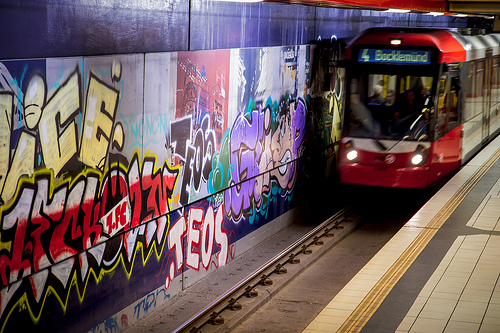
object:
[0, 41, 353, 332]
graffiti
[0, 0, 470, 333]
wall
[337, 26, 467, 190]
front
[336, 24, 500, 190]
train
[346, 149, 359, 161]
headlights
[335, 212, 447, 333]
yellow line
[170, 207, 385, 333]
track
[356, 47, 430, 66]
sign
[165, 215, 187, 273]
white letters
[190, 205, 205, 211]
red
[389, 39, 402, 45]
light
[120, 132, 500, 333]
platform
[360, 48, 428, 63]
destination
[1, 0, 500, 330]
station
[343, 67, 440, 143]
windshield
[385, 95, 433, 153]
wiper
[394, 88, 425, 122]
engineer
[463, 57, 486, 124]
windows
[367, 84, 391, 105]
passengers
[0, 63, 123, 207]
lice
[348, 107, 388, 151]
wipers